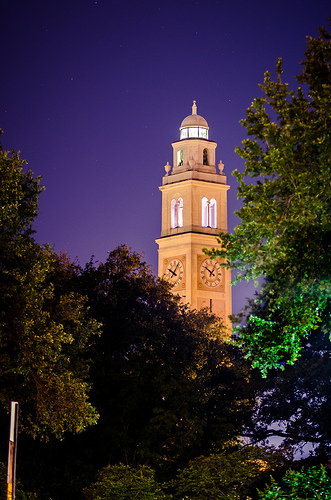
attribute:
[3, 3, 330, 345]
sky — purple, dark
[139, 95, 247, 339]
tower — illuminated, lit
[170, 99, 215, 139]
dome — lit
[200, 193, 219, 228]
window — lit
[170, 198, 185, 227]
window — lit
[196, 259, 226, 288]
clock — black, round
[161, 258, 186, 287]
clock — black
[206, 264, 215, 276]
dial — metal, black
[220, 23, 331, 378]
tree — green, tall